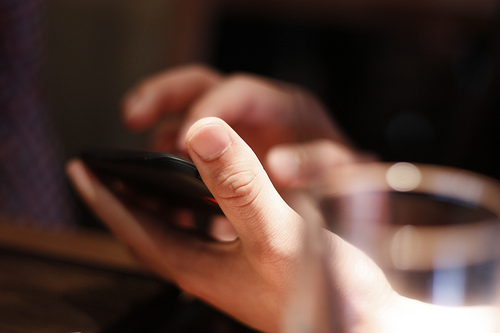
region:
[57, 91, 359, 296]
This is a hand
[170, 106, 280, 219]
This is a thumb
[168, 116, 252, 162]
This is a fingernail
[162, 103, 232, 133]
This is a nail tip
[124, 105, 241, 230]
This is a cell phone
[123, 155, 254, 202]
The phone is black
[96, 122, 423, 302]
The picture is blurry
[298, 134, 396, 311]
This is a clear glass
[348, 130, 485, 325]
The glass is clear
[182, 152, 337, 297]
The person is white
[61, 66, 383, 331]
Left and right hands of a person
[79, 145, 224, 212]
A black cell phone.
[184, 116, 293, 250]
Left hand thumb of a person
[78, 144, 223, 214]
Black cell phone in the left hand of a person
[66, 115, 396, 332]
Left hand of a person holding a phone.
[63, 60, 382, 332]
Blurry left and right hands.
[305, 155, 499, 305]
The clear rim of a glass.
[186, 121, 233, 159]
Thumb nail of a left hand thumb.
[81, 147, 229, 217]
A black cellphone in a person's left hand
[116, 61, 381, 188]
A person's blurry right hand.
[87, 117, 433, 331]
woman's handholding phone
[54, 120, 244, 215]
black cell phone in hand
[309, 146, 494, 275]
round shiny edge of cup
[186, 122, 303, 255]
thumb extended over phone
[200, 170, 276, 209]
wrinkles in person's thumb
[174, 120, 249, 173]
finger nail on person's thumb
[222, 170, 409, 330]
light shining on person's hand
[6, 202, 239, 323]
brown surface below hands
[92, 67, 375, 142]
hand above black phone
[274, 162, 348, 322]
blurry object in foreground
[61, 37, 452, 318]
hands holding a black cell phone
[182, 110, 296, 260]
thumb of a person's hand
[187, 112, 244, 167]
thumb nail on a person's hand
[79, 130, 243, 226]
black cell phone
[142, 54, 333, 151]
fingers on a person's hand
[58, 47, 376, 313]
two hands holding a phone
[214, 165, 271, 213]
knuckle on a person's thumb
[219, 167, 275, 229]
creases on a person's finger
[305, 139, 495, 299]
clear glass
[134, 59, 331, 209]
fingers on a person's hands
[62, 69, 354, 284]
A person holding a phone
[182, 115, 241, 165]
The nail on the thumb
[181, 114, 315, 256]
The thumb finger is white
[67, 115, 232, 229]
The phone is the color black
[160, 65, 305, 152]
The first finger of the person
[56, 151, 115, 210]
The tip of the finger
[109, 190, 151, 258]
The middle of the finger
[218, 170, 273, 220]
The lines on the thumb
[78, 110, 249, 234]
The phone is flat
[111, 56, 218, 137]
The middle finger of the person